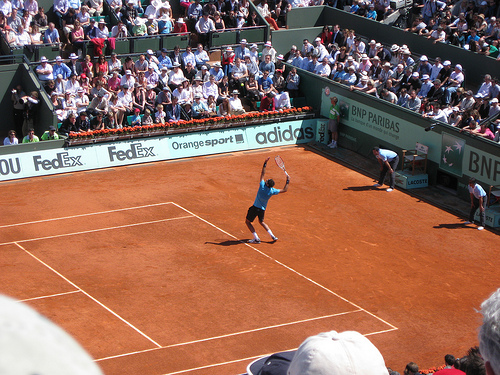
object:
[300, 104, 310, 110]
flowers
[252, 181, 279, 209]
shirt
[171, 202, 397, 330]
baseline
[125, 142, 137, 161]
letter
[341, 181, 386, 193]
shadows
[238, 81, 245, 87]
ball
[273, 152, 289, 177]
tennis racket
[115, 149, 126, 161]
black letter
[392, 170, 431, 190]
box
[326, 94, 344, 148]
man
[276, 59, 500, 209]
wall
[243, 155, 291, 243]
man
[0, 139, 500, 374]
court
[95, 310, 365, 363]
lines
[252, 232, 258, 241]
sock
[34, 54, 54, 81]
spectators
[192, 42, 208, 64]
spectators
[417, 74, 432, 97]
spectators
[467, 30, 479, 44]
spectators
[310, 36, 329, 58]
spectators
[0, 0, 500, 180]
stands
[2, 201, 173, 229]
line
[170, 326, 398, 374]
line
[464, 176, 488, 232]
judges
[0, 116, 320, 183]
advertising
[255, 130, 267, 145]
letter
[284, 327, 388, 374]
spectator's cap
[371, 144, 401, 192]
man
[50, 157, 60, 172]
letter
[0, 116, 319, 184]
wall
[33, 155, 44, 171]
black letter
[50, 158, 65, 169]
black letter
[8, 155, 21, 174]
black letter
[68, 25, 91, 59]
spectators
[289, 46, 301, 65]
spectators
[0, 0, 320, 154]
out area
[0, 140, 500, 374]
tennis court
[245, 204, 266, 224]
shorts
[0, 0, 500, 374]
match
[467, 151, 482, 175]
letter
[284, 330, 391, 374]
head